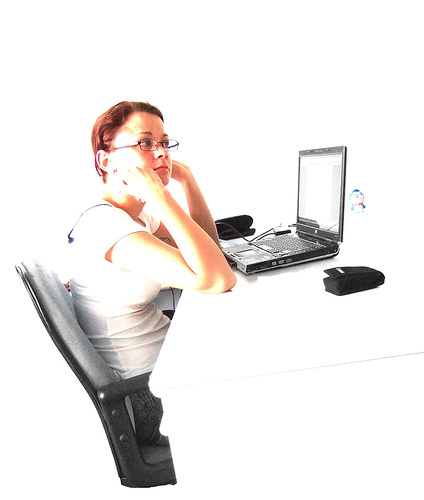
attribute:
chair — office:
[29, 272, 125, 409]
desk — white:
[168, 328, 275, 384]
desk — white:
[163, 306, 270, 367]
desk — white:
[186, 304, 390, 397]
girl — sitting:
[44, 84, 243, 460]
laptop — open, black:
[207, 134, 365, 288]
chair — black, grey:
[8, 246, 219, 499]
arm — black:
[92, 355, 188, 424]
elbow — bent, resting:
[168, 232, 244, 305]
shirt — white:
[55, 204, 169, 386]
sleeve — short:
[86, 205, 155, 271]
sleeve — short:
[132, 203, 167, 240]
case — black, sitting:
[312, 252, 396, 308]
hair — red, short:
[78, 93, 173, 177]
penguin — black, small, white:
[343, 178, 368, 224]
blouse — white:
[60, 195, 184, 373]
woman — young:
[75, 107, 213, 446]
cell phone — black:
[323, 263, 387, 299]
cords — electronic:
[241, 220, 292, 240]